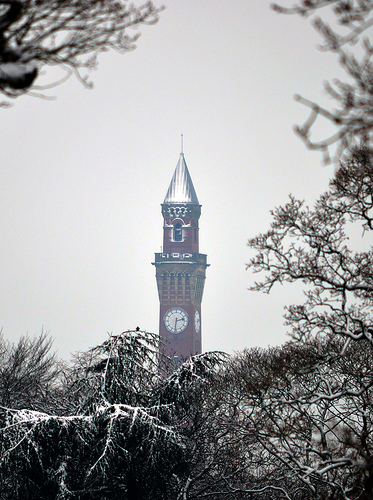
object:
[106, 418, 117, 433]
snow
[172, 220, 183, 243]
window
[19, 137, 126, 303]
white sky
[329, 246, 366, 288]
branch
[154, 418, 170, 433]
snow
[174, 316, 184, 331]
clock hands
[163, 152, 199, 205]
roof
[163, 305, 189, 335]
clock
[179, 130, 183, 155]
antennae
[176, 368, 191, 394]
snow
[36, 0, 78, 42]
branches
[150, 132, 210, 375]
brick building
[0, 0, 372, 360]
sky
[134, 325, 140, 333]
bird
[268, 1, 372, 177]
tree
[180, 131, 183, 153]
bar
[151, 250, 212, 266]
balcony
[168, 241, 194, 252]
brick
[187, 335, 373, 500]
trees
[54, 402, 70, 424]
snow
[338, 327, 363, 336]
snow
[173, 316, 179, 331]
minute hand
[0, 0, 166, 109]
trees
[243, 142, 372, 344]
trees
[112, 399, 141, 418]
snow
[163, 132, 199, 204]
spire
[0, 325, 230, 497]
tree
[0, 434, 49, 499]
branches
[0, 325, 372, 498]
some trees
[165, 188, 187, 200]
snow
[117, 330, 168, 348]
branch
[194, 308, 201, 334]
clock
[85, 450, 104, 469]
snow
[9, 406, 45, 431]
snow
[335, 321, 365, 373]
branches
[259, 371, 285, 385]
leaves